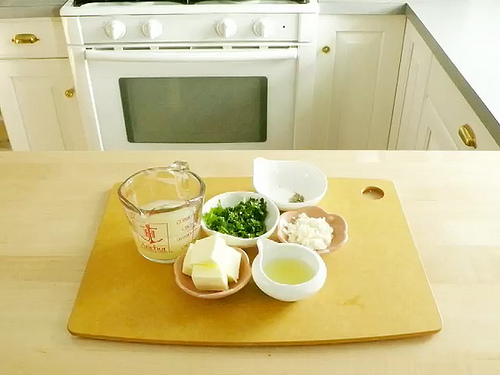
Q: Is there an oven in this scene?
A: Yes, there is an oven.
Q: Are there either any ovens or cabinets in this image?
A: Yes, there is an oven.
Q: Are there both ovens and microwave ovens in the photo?
A: No, there is an oven but no microwave ovens.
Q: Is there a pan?
A: No, there are no pans.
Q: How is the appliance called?
A: The appliance is an oven.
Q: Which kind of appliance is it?
A: The appliance is an oven.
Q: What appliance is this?
A: This is an oven.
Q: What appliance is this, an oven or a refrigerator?
A: This is an oven.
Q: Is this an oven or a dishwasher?
A: This is an oven.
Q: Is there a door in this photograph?
A: Yes, there is a door.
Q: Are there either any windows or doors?
A: Yes, there is a door.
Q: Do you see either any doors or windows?
A: Yes, there is a door.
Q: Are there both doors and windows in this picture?
A: Yes, there are both a door and a window.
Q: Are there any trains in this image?
A: No, there are no trains.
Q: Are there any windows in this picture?
A: Yes, there is a window.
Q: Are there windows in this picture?
A: Yes, there is a window.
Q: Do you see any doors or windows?
A: Yes, there is a window.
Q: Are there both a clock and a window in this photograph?
A: No, there is a window but no clocks.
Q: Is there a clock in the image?
A: No, there are no clocks.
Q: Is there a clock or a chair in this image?
A: No, there are no clocks or chairs.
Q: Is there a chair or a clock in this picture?
A: No, there are no clocks or chairs.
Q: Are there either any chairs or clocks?
A: No, there are no clocks or chairs.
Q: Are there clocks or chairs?
A: No, there are no clocks or chairs.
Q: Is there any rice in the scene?
A: Yes, there is rice.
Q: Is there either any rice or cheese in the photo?
A: Yes, there is rice.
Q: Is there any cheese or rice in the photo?
A: Yes, there is rice.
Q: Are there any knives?
A: No, there are no knives.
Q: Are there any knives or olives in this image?
A: No, there are no knives or olives.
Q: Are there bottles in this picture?
A: No, there are no bottles.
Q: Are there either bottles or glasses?
A: No, there are no bottles or glasses.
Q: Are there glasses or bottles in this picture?
A: No, there are no bottles or glasses.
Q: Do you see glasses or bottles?
A: No, there are no bottles or glasses.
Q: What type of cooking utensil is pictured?
A: The cooking utensil is a cutting board.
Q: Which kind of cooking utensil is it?
A: The cooking utensil is a cutting board.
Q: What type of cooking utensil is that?
A: This is a cutting board.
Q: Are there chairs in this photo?
A: No, there are no chairs.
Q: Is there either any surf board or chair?
A: No, there are no chairs or surfboards.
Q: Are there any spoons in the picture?
A: No, there are no spoons.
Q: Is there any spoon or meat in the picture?
A: No, there are no spoons or meat.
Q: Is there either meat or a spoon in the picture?
A: No, there are no spoons or meat.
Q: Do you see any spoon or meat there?
A: No, there are no spoons or meat.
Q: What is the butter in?
A: The butter is in the bowl.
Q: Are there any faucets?
A: No, there are no faucets.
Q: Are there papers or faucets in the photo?
A: No, there are no faucets or papers.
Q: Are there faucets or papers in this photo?
A: No, there are no faucets or papers.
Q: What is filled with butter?
A: The bowl is filled with butter.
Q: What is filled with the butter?
A: The bowl is filled with butter.